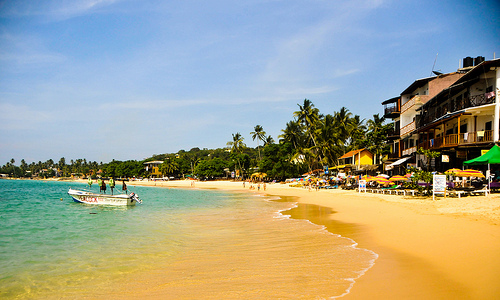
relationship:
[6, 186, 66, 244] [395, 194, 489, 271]
water coming up to sand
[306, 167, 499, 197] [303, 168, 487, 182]
people sitting underneath umbrellas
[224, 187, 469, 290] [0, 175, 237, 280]
beach near water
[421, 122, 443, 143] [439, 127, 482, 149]
people on balcony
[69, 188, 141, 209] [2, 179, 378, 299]
boat on water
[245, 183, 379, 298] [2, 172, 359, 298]
wave on ocean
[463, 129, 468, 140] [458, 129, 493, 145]
towel on balcony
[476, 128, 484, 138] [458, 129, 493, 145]
towel on balcony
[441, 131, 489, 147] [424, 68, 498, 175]
balcony on house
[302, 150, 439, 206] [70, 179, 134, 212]
people on boat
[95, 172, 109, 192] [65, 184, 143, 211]
person on boat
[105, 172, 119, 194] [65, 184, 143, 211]
person on boat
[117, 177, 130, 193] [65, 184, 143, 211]
person on boat